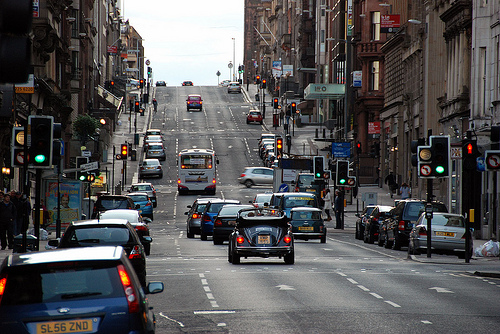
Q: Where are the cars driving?
A: On the street.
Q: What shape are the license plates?
A: Rectangle.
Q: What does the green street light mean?
A: Go.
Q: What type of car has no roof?
A: A convertible.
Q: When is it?
A: Day time.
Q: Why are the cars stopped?
A: The light is red.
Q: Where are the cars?
A: In the road.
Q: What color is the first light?
A: Green.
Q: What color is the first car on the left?
A: Blue.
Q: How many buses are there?
A: 1.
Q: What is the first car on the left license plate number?
A: SL56 ZND.